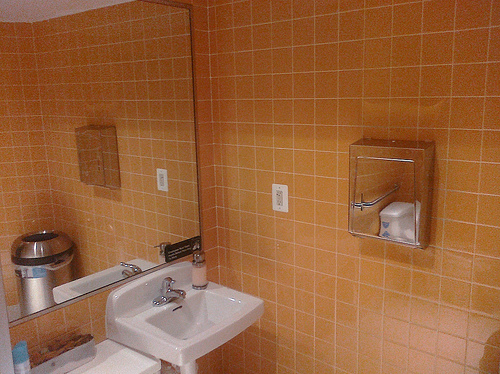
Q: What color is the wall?
A: Yellow.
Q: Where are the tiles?
A: On the wall.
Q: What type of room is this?
A: Restroom.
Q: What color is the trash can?
A: Silver.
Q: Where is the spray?
A: On the counter.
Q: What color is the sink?
A: White.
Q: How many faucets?
A: 1.